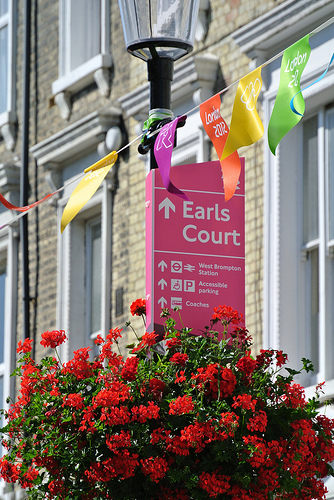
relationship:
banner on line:
[150, 115, 180, 192] [3, 17, 331, 224]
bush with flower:
[10, 327, 323, 499] [129, 296, 153, 320]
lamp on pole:
[113, 0, 204, 66] [144, 62, 178, 363]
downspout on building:
[19, 3, 34, 344] [1, 1, 333, 410]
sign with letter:
[144, 152, 248, 352] [182, 200, 194, 223]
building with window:
[1, 1, 333, 410] [301, 107, 333, 383]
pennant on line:
[263, 35, 314, 159] [3, 17, 331, 224]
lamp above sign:
[113, 0, 204, 66] [144, 152, 248, 352]